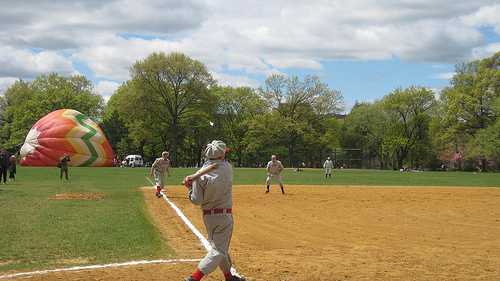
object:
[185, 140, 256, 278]
people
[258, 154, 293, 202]
people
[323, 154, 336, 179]
people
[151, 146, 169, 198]
people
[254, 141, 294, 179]
person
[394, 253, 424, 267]
dirt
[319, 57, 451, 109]
blue sky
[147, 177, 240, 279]
white line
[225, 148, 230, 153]
brim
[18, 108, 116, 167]
balloon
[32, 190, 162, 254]
ground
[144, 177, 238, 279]
line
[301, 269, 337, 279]
dirt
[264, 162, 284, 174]
shirt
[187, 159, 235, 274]
baseball uniform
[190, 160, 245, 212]
shirt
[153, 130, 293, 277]
player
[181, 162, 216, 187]
baseball bat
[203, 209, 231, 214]
belt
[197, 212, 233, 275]
pants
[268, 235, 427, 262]
floor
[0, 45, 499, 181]
trees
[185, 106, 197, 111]
leaves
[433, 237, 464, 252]
dirt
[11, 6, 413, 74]
sky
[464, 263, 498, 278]
dirt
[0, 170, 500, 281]
field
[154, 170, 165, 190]
pant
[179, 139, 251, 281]
boy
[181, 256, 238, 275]
socks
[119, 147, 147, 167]
van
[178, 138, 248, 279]
player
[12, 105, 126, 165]
parachute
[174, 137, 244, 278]
person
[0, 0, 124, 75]
clouds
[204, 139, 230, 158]
hat